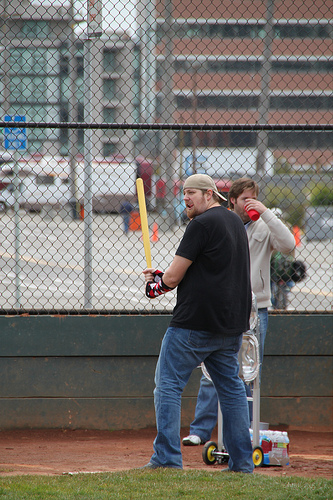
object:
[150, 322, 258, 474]
jeans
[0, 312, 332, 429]
boards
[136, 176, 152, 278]
bat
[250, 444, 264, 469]
wheel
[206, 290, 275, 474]
dolly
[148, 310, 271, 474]
pair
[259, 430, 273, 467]
bottles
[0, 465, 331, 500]
grass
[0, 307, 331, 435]
wall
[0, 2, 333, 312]
fence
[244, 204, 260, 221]
cup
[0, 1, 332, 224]
building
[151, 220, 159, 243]
cone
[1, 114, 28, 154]
sign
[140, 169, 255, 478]
guy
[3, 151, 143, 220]
motorhome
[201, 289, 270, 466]
handtruck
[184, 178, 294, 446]
guy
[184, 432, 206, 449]
shoe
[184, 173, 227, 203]
cap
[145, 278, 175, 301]
gloves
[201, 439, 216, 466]
wheel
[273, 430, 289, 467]
bottle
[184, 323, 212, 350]
pocket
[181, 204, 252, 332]
back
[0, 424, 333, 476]
dirt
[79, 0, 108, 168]
pole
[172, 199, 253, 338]
t-shirt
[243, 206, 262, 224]
red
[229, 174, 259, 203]
hair